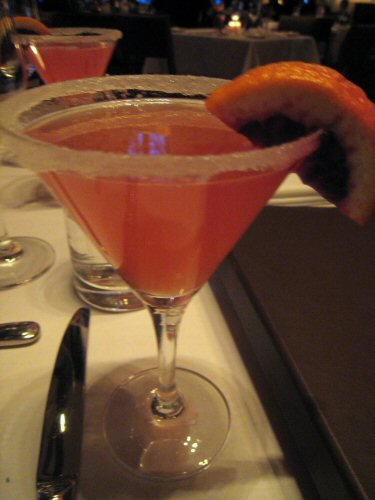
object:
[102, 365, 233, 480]
base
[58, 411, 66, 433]
reflection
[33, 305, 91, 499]
knife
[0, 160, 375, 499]
table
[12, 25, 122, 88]
drink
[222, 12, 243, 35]
lights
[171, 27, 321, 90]
table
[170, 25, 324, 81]
tablecloth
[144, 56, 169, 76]
chair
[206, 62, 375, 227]
fruit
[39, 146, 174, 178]
sugar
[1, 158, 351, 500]
table cloth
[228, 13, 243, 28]
candle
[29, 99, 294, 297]
cocktail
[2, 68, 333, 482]
cup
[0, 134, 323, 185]
salt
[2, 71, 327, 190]
rim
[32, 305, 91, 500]
silverware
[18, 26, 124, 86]
glass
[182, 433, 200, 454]
reflection